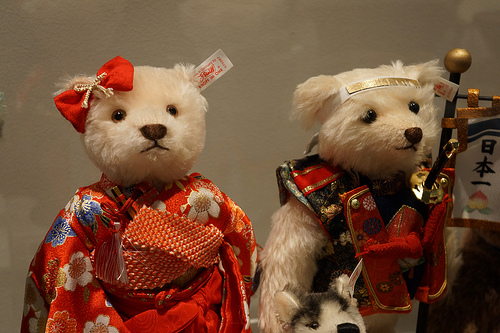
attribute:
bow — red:
[51, 54, 137, 136]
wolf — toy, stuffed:
[274, 271, 372, 332]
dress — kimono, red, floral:
[19, 173, 262, 333]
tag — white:
[189, 46, 235, 94]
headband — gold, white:
[333, 75, 429, 110]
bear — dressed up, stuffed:
[252, 54, 465, 332]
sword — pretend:
[406, 136, 461, 218]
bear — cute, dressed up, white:
[16, 45, 265, 331]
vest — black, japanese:
[273, 149, 424, 312]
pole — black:
[419, 70, 467, 228]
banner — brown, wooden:
[437, 86, 500, 237]